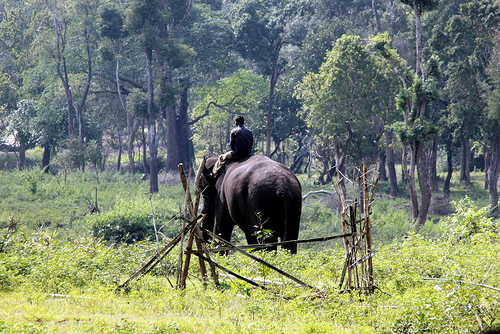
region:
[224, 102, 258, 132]
the head of a man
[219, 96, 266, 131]
the hair of a man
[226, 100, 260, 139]
the small head of a man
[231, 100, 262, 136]
the round head of a man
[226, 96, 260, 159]
the back of a man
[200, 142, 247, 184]
the leg of a man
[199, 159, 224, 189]
the foot of a man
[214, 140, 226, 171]
the knee of a man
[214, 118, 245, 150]
the arm of a man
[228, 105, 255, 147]
the shoulder of a man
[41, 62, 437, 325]
A person is on an elephant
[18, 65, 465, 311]
A person is out in the forest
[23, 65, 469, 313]
An elephant is carrying a person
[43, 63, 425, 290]
An elephant is walking around slowly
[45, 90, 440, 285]
An elephant is close to some trees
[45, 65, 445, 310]
An elephant is going for a walk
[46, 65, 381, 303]
An elephant is out in the daytime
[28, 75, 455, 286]
A person is looking for somebody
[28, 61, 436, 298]
A person is having a good time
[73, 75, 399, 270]
An elephant is walking in the weeds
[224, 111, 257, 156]
A person sitting on an elephant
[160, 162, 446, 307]
sticks surround the elephant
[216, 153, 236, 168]
The pants the man is wearing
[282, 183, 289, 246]
The tail of the elephant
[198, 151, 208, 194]
The ear of the elephant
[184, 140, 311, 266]
An elephant in the feild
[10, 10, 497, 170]
Trees surrounding the feild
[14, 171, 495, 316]
A green and grassy feild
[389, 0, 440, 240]
The cloeset tree that is twisted a little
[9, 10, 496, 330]
A forest that has a man and an elephant in it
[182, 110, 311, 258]
Man riding large animal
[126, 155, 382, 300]
Wood fence behind elephant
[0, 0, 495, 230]
Large number of trees in the forest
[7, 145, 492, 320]
Grass is grown up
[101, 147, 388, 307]
Fence is falling down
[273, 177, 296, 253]
Elephant's tail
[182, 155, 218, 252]
Elephant's trunk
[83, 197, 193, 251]
Large green bush in front of elephant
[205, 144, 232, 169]
Man's khaki pants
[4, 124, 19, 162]
Small clearing through the trees